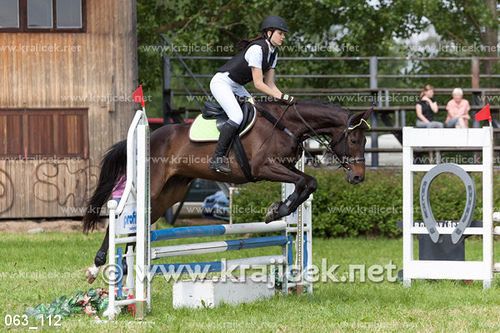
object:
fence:
[103, 109, 313, 321]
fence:
[400, 124, 495, 289]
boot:
[206, 121, 240, 176]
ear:
[263, 30, 273, 40]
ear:
[343, 109, 366, 130]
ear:
[359, 107, 376, 122]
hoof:
[263, 200, 291, 225]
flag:
[130, 83, 147, 111]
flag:
[473, 102, 493, 127]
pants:
[206, 71, 257, 125]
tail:
[78, 139, 126, 237]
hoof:
[81, 266, 101, 285]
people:
[442, 85, 472, 128]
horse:
[80, 95, 375, 286]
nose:
[350, 174, 362, 184]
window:
[55, 0, 80, 29]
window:
[24, 0, 54, 29]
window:
[0, 0, 21, 30]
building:
[0, 0, 144, 222]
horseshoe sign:
[416, 160, 474, 244]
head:
[323, 105, 375, 186]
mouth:
[344, 171, 364, 185]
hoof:
[92, 249, 112, 267]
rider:
[205, 16, 295, 176]